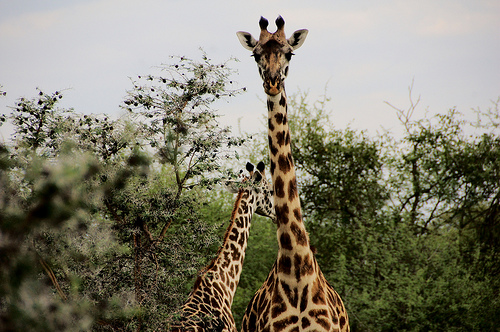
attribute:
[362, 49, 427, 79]
sky — blue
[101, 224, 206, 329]
thorns — white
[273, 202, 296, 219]
spot — brown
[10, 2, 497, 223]
sky — blue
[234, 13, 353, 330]
giraffe — adult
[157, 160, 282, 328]
giraffe — adult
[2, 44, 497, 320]
trees — tall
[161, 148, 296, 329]
giraffe — juvenile